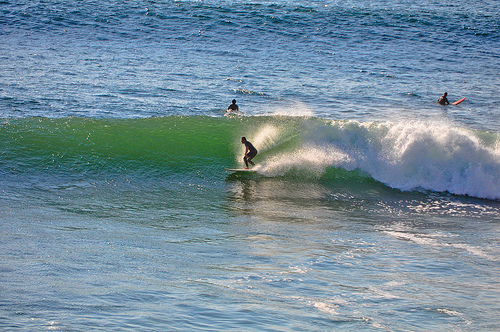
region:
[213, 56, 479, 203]
three surfers in the ocean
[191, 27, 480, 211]
three people in the water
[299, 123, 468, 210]
white crest of the waves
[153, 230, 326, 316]
calm part of the ocean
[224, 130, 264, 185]
surfer riding on a wave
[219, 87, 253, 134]
surfer behind the wave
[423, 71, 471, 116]
surfer waiting for a wave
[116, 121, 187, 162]
green part of the ocean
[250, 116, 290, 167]
white spray from the waves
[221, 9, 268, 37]
dark blue part of the ocean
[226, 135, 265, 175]
man surfing in green water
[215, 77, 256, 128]
man surfing in green water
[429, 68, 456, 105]
man surfing in green water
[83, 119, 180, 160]
green water in wave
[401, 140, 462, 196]
white water of crashing wave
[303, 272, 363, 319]
white foam on water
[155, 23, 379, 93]
calm water behind wave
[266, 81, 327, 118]
water spraying up in air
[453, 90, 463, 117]
red surfboard in water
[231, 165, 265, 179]
white surfboard in water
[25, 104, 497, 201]
the wave is green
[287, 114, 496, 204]
the foam is white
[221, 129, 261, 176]
a man on a surfboard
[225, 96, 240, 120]
a man behind the wave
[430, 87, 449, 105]
a man in the water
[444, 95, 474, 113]
he is holding a red board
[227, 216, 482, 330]
small waves in the water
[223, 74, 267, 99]
a small wave behind the man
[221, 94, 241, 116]
a man in half the water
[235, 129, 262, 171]
the man crouched over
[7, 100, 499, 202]
Small green wave in the ocean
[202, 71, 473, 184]
Three surfers in the ocean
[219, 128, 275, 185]
Man riding a wave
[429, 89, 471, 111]
Man with red surfboard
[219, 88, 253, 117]
Silhouette of surfboarder in the distance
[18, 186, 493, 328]
Small ripples in the water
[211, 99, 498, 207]
White ocean spray from the waves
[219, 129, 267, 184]
Man on white surfboard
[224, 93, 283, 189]
Two surfers parallel to each other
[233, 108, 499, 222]
Small white wave following surfer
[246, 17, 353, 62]
ripples in ocean water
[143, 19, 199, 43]
ripples in ocean water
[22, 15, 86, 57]
ripples in ocean water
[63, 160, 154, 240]
ripples in ocean water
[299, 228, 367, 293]
ripples in ocean water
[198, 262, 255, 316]
ripples in ocean water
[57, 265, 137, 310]
ripples in ocean water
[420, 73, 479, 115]
person riding on surfboard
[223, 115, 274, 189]
person riding on surfboard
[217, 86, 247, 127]
person riding on surfboard